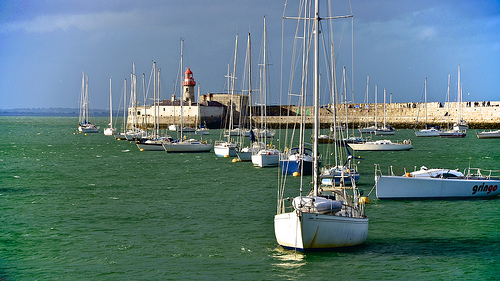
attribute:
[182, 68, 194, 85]
lighthouse — red, white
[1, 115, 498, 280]
water — green, calm, blue, still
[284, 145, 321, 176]
sailboat — blue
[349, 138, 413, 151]
boat — docked, white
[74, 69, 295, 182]
boats — stationary, docked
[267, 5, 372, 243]
boat — reflecting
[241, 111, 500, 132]
wall — cement, damaged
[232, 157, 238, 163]
bouys — yellow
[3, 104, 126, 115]
hills — forrested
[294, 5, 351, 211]
sails — tall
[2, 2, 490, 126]
clouds — few, clear, sunny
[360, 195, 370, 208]
anchors — yellow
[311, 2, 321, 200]
pole — metal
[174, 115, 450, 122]
people — standing